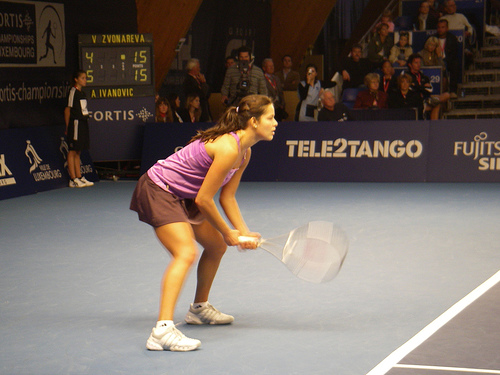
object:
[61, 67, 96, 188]
ballboy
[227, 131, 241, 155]
strap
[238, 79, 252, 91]
camera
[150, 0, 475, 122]
crowd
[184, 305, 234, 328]
shoes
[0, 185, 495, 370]
tennis court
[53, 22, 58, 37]
racket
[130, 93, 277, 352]
girl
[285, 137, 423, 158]
tele2tango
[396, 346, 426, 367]
corner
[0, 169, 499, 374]
court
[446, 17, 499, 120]
stairs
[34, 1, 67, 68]
advertisement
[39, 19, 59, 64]
player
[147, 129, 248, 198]
pink shirt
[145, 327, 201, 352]
shoe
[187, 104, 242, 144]
pony tail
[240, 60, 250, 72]
camera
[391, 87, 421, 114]
shirt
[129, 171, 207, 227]
tennis skirt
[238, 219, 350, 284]
racket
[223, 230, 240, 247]
hand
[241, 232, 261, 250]
hand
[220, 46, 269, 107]
cameraman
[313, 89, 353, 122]
person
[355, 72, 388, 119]
person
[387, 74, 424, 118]
person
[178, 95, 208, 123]
person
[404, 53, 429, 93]
person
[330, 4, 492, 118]
stands